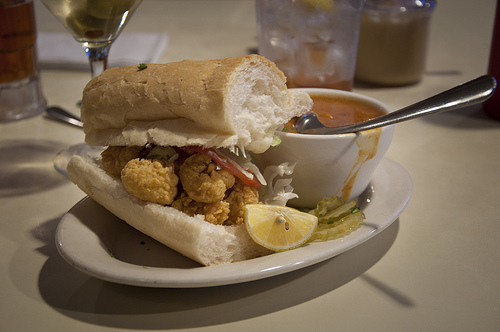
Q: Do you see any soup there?
A: Yes, there is soup.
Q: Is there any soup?
A: Yes, there is soup.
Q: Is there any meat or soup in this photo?
A: Yes, there is soup.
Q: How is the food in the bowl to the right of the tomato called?
A: The food is soup.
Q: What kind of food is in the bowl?
A: The food is soup.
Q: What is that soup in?
A: The soup is in the bowl.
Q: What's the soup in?
A: The soup is in the bowl.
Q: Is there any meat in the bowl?
A: No, there is soup in the bowl.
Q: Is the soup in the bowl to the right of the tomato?
A: Yes, the soup is in the bowl.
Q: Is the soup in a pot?
A: No, the soup is in the bowl.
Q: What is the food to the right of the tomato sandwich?
A: The food is soup.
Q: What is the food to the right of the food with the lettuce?
A: The food is soup.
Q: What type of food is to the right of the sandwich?
A: The food is soup.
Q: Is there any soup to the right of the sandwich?
A: Yes, there is soup to the right of the sandwich.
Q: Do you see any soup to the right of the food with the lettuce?
A: Yes, there is soup to the right of the sandwich.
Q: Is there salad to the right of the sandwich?
A: No, there is soup to the right of the sandwich.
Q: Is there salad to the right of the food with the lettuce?
A: No, there is soup to the right of the sandwich.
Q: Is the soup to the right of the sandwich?
A: Yes, the soup is to the right of the sandwich.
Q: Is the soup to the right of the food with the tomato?
A: Yes, the soup is to the right of the sandwich.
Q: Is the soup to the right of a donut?
A: No, the soup is to the right of the sandwich.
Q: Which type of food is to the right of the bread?
A: The food is soup.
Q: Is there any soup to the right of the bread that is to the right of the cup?
A: Yes, there is soup to the right of the bread.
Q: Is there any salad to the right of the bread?
A: No, there is soup to the right of the bread.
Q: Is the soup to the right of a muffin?
A: No, the soup is to the right of a bread.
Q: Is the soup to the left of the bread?
A: No, the soup is to the right of the bread.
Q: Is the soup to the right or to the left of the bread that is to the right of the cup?
A: The soup is to the right of the bread.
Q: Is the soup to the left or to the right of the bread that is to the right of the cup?
A: The soup is to the right of the bread.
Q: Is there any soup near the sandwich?
A: Yes, there is soup near the sandwich.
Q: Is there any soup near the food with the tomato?
A: Yes, there is soup near the sandwich.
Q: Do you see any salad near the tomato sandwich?
A: No, there is soup near the sandwich.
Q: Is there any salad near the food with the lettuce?
A: No, there is soup near the sandwich.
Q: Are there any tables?
A: Yes, there is a table.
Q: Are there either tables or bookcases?
A: Yes, there is a table.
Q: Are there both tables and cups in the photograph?
A: Yes, there are both a table and a cup.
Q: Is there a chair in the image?
A: No, there are no chairs.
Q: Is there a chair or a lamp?
A: No, there are no chairs or lamps.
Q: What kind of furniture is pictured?
A: The furniture is a table.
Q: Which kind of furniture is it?
A: The piece of furniture is a table.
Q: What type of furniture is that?
A: This is a table.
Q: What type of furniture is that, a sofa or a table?
A: This is a table.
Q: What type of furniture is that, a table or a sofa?
A: This is a table.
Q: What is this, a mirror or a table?
A: This is a table.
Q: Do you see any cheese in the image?
A: No, there is no cheese.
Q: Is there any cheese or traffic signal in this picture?
A: No, there are no cheese or traffic lights.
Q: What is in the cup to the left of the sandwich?
A: The liquid is in the cup.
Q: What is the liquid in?
A: The liquid is in the cup.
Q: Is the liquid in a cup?
A: Yes, the liquid is in a cup.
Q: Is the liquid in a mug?
A: No, the liquid is in a cup.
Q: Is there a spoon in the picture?
A: Yes, there is a spoon.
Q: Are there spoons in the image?
A: Yes, there is a spoon.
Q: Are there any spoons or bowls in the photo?
A: Yes, there is a spoon.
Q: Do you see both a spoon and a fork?
A: No, there is a spoon but no forks.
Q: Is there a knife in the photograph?
A: No, there are no knives.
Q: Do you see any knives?
A: No, there are no knives.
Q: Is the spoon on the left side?
A: No, the spoon is on the right of the image.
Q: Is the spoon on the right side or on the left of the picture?
A: The spoon is on the right of the image.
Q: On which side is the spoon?
A: The spoon is on the right of the image.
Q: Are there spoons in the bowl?
A: Yes, there is a spoon in the bowl.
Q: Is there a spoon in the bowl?
A: Yes, there is a spoon in the bowl.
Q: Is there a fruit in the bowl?
A: No, there is a spoon in the bowl.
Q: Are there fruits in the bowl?
A: No, there is a spoon in the bowl.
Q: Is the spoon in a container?
A: No, the spoon is in a bowl.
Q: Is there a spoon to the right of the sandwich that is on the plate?
A: Yes, there is a spoon to the right of the sandwich.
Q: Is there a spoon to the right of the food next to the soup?
A: Yes, there is a spoon to the right of the sandwich.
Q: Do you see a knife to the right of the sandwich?
A: No, there is a spoon to the right of the sandwich.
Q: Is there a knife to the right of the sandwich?
A: No, there is a spoon to the right of the sandwich.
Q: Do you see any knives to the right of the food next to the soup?
A: No, there is a spoon to the right of the sandwich.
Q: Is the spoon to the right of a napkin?
A: No, the spoon is to the right of the sandwich.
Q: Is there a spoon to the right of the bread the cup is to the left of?
A: Yes, there is a spoon to the right of the bread.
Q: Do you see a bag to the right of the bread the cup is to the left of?
A: No, there is a spoon to the right of the bread.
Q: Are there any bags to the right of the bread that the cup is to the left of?
A: No, there is a spoon to the right of the bread.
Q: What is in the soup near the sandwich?
A: The spoon is in the soup.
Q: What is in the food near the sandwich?
A: The spoon is in the soup.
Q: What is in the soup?
A: The spoon is in the soup.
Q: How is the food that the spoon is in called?
A: The food is soup.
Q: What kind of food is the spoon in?
A: The spoon is in the soup.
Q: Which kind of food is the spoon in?
A: The spoon is in the soup.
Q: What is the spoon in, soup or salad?
A: The spoon is in soup.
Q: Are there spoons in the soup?
A: Yes, there is a spoon in the soup.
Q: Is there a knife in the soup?
A: No, there is a spoon in the soup.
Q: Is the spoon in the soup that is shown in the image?
A: Yes, the spoon is in the soup.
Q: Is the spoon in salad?
A: No, the spoon is in the soup.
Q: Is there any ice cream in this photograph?
A: No, there is no ice cream.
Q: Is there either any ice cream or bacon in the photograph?
A: No, there are no ice cream or bacon.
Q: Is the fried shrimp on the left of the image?
A: Yes, the shrimp is on the left of the image.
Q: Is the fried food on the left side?
A: Yes, the shrimp is on the left of the image.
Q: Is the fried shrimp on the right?
A: No, the shrimp is on the left of the image.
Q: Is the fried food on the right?
A: No, the shrimp is on the left of the image.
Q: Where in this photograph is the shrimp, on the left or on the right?
A: The shrimp is on the left of the image.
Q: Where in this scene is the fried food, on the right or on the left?
A: The shrimp is on the left of the image.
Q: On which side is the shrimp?
A: The shrimp is on the left of the image.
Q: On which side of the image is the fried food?
A: The shrimp is on the left of the image.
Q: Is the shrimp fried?
A: Yes, the shrimp is fried.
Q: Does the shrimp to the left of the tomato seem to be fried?
A: Yes, the shrimp is fried.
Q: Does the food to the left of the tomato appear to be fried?
A: Yes, the shrimp is fried.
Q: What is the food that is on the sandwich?
A: The food is shrimp.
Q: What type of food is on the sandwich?
A: The food is shrimp.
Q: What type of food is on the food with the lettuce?
A: The food is shrimp.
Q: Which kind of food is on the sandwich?
A: The food is shrimp.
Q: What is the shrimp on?
A: The shrimp is on the sandwich.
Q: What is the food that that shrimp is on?
A: The food is a sandwich.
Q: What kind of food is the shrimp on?
A: The shrimp is on the sandwich.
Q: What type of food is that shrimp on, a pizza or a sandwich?
A: The shrimp is on a sandwich.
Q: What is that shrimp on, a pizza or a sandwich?
A: The shrimp is on a sandwich.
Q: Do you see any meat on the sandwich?
A: No, there is shrimp on the sandwich.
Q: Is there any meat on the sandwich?
A: No, there is shrimp on the sandwich.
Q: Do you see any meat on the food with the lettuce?
A: No, there is shrimp on the sandwich.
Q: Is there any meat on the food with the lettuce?
A: No, there is shrimp on the sandwich.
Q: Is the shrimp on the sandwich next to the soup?
A: Yes, the shrimp is on the sandwich.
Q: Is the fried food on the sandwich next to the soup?
A: Yes, the shrimp is on the sandwich.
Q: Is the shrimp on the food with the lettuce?
A: Yes, the shrimp is on the sandwich.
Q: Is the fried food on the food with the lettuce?
A: Yes, the shrimp is on the sandwich.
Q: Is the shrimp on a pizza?
A: No, the shrimp is on the sandwich.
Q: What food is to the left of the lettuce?
A: The food is shrimp.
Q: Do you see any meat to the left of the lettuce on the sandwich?
A: No, there is shrimp to the left of the lettuce.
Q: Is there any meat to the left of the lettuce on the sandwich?
A: No, there is shrimp to the left of the lettuce.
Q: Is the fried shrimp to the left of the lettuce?
A: Yes, the shrimp is to the left of the lettuce.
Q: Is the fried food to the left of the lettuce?
A: Yes, the shrimp is to the left of the lettuce.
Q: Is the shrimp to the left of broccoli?
A: No, the shrimp is to the left of the lettuce.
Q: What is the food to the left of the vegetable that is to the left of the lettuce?
A: The food is shrimp.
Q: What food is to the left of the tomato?
A: The food is shrimp.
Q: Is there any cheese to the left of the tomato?
A: No, there is shrimp to the left of the tomato.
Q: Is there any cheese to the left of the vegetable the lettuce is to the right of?
A: No, there is shrimp to the left of the tomato.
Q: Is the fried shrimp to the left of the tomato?
A: Yes, the shrimp is to the left of the tomato.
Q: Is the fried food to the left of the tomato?
A: Yes, the shrimp is to the left of the tomato.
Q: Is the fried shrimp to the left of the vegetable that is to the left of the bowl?
A: Yes, the shrimp is to the left of the tomato.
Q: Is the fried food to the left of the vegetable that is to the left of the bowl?
A: Yes, the shrimp is to the left of the tomato.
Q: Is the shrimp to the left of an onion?
A: No, the shrimp is to the left of the tomato.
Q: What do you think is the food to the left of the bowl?
A: The food is shrimp.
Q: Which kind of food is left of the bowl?
A: The food is shrimp.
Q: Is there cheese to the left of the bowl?
A: No, there is shrimp to the left of the bowl.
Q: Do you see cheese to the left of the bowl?
A: No, there is shrimp to the left of the bowl.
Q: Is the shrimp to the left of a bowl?
A: Yes, the shrimp is to the left of a bowl.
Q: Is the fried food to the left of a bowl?
A: Yes, the shrimp is to the left of a bowl.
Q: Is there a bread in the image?
A: Yes, there is a bread.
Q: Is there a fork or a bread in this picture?
A: Yes, there is a bread.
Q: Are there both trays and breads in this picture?
A: No, there is a bread but no trays.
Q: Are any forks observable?
A: No, there are no forks.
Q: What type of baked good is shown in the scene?
A: The baked good is a bread.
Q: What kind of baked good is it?
A: The food is a bread.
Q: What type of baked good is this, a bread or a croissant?
A: That is a bread.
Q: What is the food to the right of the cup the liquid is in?
A: The food is a bread.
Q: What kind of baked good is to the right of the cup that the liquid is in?
A: The food is a bread.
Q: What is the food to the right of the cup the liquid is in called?
A: The food is a bread.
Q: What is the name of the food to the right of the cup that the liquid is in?
A: The food is a bread.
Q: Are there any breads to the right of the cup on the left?
A: Yes, there is a bread to the right of the cup.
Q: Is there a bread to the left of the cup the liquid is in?
A: No, the bread is to the right of the cup.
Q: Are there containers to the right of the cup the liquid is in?
A: No, there is a bread to the right of the cup.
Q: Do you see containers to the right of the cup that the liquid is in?
A: No, there is a bread to the right of the cup.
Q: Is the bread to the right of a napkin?
A: No, the bread is to the right of the cup.